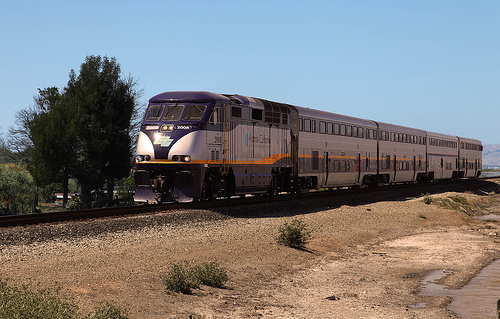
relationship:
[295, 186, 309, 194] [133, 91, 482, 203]
wheel on train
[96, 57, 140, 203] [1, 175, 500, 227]
tree alongside track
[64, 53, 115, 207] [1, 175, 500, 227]
tree behind track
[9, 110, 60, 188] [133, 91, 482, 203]
tree alongside train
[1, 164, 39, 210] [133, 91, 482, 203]
tree near train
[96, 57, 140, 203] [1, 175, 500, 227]
tree near track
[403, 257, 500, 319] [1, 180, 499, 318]
water on ground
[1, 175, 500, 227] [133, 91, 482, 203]
track under train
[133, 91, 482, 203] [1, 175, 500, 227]
train on track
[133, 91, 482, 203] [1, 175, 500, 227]
train on top of track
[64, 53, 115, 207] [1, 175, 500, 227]
tree beside track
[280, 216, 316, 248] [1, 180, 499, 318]
bush on ground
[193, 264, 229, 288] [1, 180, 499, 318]
bush on ground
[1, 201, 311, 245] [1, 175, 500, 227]
gravel along track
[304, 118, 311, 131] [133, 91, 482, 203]
window on train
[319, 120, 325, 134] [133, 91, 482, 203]
window on train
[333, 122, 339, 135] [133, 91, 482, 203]
window on train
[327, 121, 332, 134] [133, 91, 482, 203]
window on train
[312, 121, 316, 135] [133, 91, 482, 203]
window on train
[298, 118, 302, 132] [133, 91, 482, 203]
window on train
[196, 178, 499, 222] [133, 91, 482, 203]
shadow of train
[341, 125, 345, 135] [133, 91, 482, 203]
window on train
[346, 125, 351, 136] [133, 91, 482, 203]
window on train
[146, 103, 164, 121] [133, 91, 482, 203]
window on train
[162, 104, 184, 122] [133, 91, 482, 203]
window on train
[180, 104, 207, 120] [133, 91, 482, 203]
window on train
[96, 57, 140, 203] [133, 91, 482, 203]
tree beside train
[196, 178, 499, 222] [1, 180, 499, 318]
shadow on ground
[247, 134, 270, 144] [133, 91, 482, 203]
letters on train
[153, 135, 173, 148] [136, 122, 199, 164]
letters on front